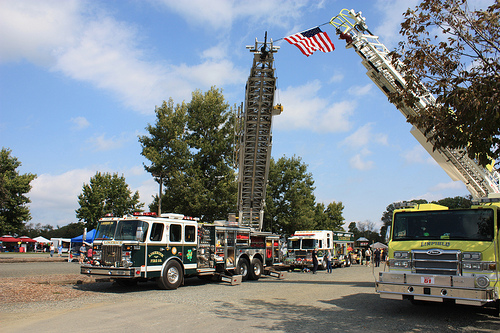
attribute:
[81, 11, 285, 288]
fire truck — parked, white, green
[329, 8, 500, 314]
fire truck — parked, yellow, bright yellow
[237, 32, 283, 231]
ladder — raised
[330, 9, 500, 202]
ladder — raised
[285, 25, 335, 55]
flag — american, flying, red,white, blue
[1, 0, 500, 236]
sky — blue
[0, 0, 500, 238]
clouds — white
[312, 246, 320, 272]
person — standing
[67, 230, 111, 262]
tent — blue